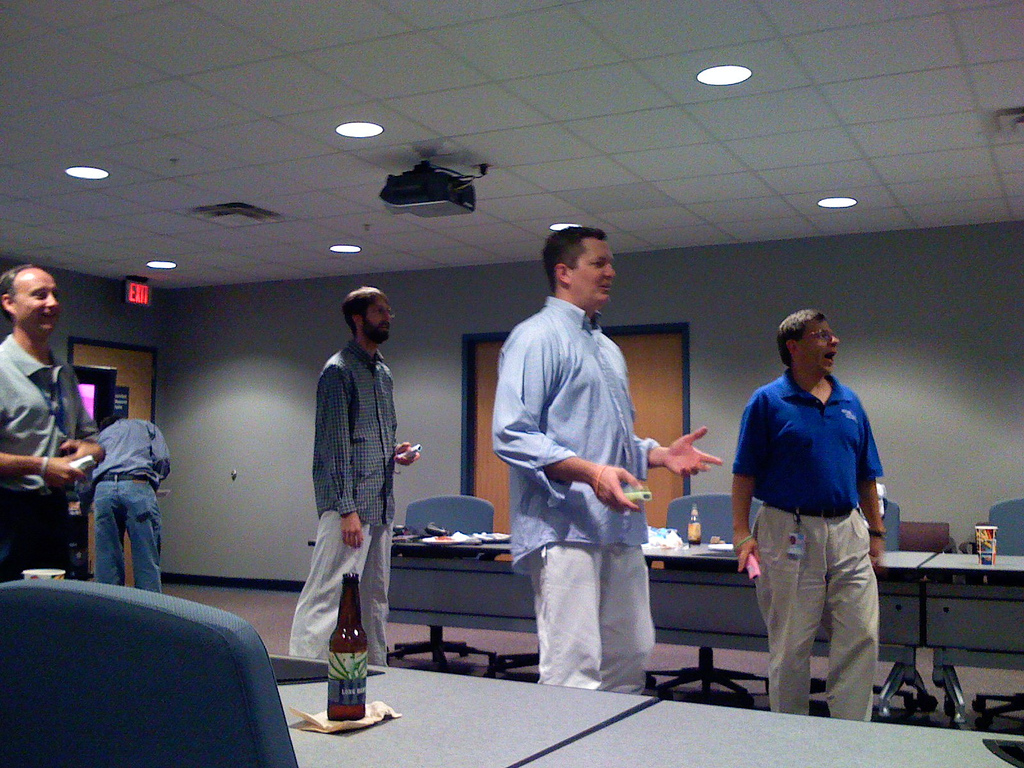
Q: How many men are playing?
A: 4.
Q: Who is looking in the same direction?
A: The 4 guys.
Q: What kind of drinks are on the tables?
A: Bottles of beer.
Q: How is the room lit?
A: Overhead lights.